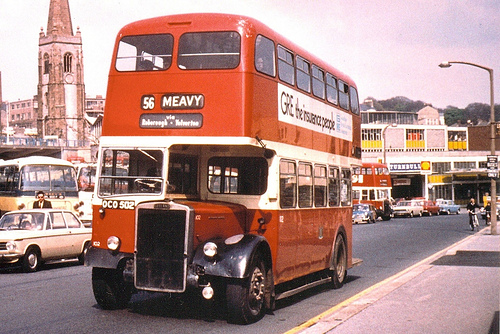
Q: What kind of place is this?
A: It is a city.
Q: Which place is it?
A: It is a city.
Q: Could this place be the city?
A: Yes, it is the city.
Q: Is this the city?
A: Yes, it is the city.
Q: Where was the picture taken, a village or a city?
A: It was taken at a city.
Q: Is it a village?
A: No, it is a city.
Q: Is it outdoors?
A: Yes, it is outdoors.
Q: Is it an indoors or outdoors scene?
A: It is outdoors.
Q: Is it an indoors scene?
A: No, it is outdoors.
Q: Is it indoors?
A: No, it is outdoors.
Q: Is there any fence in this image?
A: No, there are no fences.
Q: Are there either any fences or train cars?
A: No, there are no fences or train cars.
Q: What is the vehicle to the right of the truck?
A: The vehicle is a car.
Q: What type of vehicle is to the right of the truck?
A: The vehicle is a car.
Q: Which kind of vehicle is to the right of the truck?
A: The vehicle is a car.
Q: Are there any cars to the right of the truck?
A: Yes, there is a car to the right of the truck.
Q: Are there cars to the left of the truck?
A: No, the car is to the right of the truck.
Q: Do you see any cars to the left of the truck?
A: No, the car is to the right of the truck.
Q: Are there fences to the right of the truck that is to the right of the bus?
A: No, there is a car to the right of the truck.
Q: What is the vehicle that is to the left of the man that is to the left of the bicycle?
A: The vehicle is a car.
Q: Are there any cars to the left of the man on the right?
A: Yes, there is a car to the left of the man.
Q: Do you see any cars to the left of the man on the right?
A: Yes, there is a car to the left of the man.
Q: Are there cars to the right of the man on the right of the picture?
A: No, the car is to the left of the man.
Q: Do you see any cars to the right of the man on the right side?
A: No, the car is to the left of the man.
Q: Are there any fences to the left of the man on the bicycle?
A: No, there is a car to the left of the man.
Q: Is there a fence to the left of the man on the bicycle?
A: No, there is a car to the left of the man.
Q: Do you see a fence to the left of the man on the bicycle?
A: No, there is a car to the left of the man.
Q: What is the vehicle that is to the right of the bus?
A: The vehicle is a car.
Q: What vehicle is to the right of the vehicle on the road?
A: The vehicle is a car.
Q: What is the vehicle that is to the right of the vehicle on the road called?
A: The vehicle is a car.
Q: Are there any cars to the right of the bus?
A: Yes, there is a car to the right of the bus.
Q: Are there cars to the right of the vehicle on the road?
A: Yes, there is a car to the right of the bus.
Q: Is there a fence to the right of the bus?
A: No, there is a car to the right of the bus.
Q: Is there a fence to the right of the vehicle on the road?
A: No, there is a car to the right of the bus.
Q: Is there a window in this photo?
A: Yes, there is a window.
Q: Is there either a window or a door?
A: Yes, there is a window.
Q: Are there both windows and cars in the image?
A: Yes, there are both a window and a car.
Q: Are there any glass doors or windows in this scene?
A: Yes, there is a glass window.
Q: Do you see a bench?
A: No, there are no benches.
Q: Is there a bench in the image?
A: No, there are no benches.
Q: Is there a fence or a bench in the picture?
A: No, there are no benches or fences.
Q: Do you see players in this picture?
A: No, there are no players.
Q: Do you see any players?
A: No, there are no players.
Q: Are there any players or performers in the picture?
A: No, there are no players or performers.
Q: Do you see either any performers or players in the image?
A: No, there are no players or performers.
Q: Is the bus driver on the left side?
A: Yes, the bus driver is on the left of the image.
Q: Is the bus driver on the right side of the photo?
A: No, the bus driver is on the left of the image.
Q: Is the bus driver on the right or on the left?
A: The bus driver is on the left of the image.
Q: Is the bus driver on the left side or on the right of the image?
A: The bus driver is on the left of the image.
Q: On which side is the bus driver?
A: The bus driver is on the left of the image.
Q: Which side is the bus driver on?
A: The bus driver is on the left of the image.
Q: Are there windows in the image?
A: Yes, there are windows.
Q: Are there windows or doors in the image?
A: Yes, there are windows.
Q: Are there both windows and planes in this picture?
A: No, there are windows but no airplanes.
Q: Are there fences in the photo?
A: No, there are no fences.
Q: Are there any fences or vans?
A: No, there are no fences or vans.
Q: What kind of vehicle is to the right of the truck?
A: The vehicles are cars.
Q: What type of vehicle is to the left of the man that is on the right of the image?
A: The vehicles are cars.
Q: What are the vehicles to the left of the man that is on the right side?
A: The vehicles are cars.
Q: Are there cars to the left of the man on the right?
A: Yes, there are cars to the left of the man.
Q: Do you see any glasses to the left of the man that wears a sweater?
A: No, there are cars to the left of the man.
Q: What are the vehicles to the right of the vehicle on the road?
A: The vehicles are cars.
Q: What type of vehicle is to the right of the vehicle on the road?
A: The vehicles are cars.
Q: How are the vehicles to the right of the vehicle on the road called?
A: The vehicles are cars.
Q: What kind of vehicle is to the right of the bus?
A: The vehicles are cars.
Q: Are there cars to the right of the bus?
A: Yes, there are cars to the right of the bus.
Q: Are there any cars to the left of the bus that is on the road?
A: No, the cars are to the right of the bus.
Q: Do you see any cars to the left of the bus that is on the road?
A: No, the cars are to the right of the bus.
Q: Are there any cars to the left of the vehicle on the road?
A: No, the cars are to the right of the bus.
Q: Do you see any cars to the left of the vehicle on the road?
A: No, the cars are to the right of the bus.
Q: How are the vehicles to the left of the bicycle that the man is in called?
A: The vehicles are cars.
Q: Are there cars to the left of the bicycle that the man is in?
A: Yes, there are cars to the left of the bicycle.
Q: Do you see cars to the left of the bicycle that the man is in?
A: Yes, there are cars to the left of the bicycle.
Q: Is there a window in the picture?
A: Yes, there is a window.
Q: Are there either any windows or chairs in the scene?
A: Yes, there is a window.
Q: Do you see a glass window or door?
A: Yes, there is a glass window.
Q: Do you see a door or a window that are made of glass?
A: Yes, the window is made of glass.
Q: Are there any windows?
A: Yes, there is a window.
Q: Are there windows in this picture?
A: Yes, there is a window.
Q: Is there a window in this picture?
A: Yes, there is a window.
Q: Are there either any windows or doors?
A: Yes, there is a window.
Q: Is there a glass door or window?
A: Yes, there is a glass window.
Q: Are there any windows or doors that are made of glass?
A: Yes, the window is made of glass.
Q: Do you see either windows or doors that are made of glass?
A: Yes, the window is made of glass.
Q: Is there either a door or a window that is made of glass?
A: Yes, the window is made of glass.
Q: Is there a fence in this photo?
A: No, there are no fences.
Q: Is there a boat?
A: No, there are no boats.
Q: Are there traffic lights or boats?
A: No, there are no boats or traffic lights.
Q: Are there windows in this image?
A: Yes, there is a window.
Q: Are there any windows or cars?
A: Yes, there is a window.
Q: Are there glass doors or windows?
A: Yes, there is a glass window.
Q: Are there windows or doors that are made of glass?
A: Yes, the window is made of glass.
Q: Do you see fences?
A: No, there are no fences.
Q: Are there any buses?
A: Yes, there is a bus.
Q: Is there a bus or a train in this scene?
A: Yes, there is a bus.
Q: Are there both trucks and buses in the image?
A: Yes, there are both a bus and a truck.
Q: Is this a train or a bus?
A: This is a bus.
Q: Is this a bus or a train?
A: This is a bus.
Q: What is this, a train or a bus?
A: This is a bus.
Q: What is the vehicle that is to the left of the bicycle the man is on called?
A: The vehicle is a bus.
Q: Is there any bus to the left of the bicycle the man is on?
A: Yes, there is a bus to the left of the bicycle.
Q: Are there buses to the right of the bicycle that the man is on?
A: No, the bus is to the left of the bicycle.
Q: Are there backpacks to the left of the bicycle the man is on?
A: No, there is a bus to the left of the bicycle.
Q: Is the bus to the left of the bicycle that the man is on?
A: Yes, the bus is to the left of the bicycle.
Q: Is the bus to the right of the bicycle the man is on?
A: No, the bus is to the left of the bicycle.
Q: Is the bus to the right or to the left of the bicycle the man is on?
A: The bus is to the left of the bicycle.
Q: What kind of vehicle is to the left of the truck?
A: The vehicle is a bus.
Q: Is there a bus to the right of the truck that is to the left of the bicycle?
A: No, the bus is to the left of the truck.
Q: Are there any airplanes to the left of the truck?
A: No, there is a bus to the left of the truck.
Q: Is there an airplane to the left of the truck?
A: No, there is a bus to the left of the truck.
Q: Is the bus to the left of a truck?
A: Yes, the bus is to the left of a truck.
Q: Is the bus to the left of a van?
A: No, the bus is to the left of a truck.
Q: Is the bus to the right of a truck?
A: No, the bus is to the left of a truck.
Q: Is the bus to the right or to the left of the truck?
A: The bus is to the left of the truck.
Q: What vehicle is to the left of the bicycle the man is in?
A: The vehicle is a bus.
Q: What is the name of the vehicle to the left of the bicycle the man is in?
A: The vehicle is a bus.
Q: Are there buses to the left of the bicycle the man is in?
A: Yes, there is a bus to the left of the bicycle.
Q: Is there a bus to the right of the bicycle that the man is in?
A: No, the bus is to the left of the bicycle.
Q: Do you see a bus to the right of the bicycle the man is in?
A: No, the bus is to the left of the bicycle.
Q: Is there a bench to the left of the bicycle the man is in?
A: No, there is a bus to the left of the bicycle.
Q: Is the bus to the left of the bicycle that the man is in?
A: Yes, the bus is to the left of the bicycle.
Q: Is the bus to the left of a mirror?
A: No, the bus is to the left of the bicycle.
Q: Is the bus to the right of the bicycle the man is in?
A: No, the bus is to the left of the bicycle.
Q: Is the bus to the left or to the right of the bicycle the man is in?
A: The bus is to the left of the bicycle.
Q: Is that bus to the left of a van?
A: No, the bus is to the left of the car.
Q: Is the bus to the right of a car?
A: No, the bus is to the left of a car.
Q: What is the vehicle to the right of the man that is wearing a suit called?
A: The vehicle is a bus.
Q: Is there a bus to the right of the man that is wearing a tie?
A: Yes, there is a bus to the right of the man.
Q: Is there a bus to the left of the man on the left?
A: No, the bus is to the right of the man.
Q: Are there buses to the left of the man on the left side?
A: No, the bus is to the right of the man.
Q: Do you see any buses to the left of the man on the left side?
A: No, the bus is to the right of the man.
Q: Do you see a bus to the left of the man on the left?
A: No, the bus is to the right of the man.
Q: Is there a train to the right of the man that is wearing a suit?
A: No, there is a bus to the right of the man.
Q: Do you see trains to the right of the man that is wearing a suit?
A: No, there is a bus to the right of the man.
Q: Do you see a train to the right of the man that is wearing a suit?
A: No, there is a bus to the right of the man.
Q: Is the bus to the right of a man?
A: Yes, the bus is to the right of a man.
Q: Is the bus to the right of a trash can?
A: No, the bus is to the right of a man.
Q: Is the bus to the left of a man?
A: No, the bus is to the right of a man.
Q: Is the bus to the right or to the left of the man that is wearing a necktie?
A: The bus is to the right of the man.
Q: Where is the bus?
A: The bus is on the road.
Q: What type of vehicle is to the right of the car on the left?
A: The vehicle is a bus.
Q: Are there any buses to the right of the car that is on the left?
A: Yes, there is a bus to the right of the car.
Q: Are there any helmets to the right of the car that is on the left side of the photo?
A: No, there is a bus to the right of the car.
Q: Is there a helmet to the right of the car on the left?
A: No, there is a bus to the right of the car.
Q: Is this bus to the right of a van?
A: No, the bus is to the right of the car.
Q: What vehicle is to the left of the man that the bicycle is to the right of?
A: The vehicle is a bus.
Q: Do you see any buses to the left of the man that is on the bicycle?
A: Yes, there is a bus to the left of the man.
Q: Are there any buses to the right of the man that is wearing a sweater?
A: No, the bus is to the left of the man.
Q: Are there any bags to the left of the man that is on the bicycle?
A: No, there is a bus to the left of the man.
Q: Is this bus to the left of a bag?
A: No, the bus is to the left of a man.